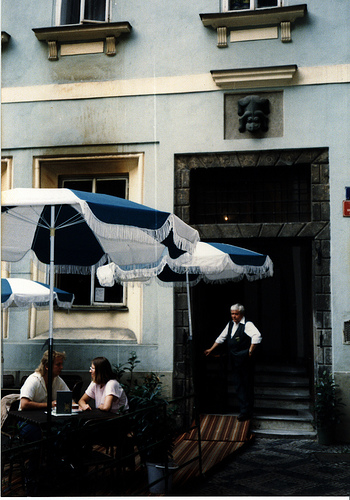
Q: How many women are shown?
A: One.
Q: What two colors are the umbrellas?
A: Blue and white.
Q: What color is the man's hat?
A: White.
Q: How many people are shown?
A: Three.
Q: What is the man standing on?
A: Stairs.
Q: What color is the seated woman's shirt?
A: Pink.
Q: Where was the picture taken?
A: A cafe.